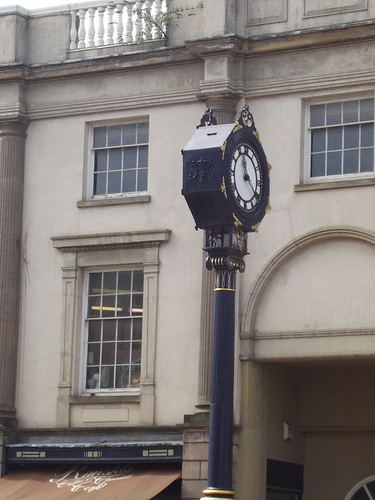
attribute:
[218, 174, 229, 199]
details — gold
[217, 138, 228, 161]
details — gold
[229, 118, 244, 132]
details — gold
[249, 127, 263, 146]
details — gold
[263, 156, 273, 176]
details — gold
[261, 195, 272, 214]
details — gold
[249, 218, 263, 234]
details — gold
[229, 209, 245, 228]
details — gold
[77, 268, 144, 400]
window — white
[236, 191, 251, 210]
numerals — roman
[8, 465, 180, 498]
awning — brown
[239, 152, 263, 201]
hands — black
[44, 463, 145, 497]
writing — white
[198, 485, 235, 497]
stripes — gold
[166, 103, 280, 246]
clock — black, white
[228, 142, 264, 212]
clock face — white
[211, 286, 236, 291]
stripe — gold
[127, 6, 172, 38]
tree — green  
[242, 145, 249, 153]
roman numeral — black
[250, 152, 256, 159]
roman numeral — black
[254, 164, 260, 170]
roman numeral — black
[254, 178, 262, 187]
roman numeral — black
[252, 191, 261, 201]
roman numeral — black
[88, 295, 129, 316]
light — hanging  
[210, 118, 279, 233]
clock — big  , blue  , white  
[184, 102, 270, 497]
clock — tall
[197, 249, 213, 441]
column — stone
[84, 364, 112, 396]
fan — small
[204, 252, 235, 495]
pole — gold, black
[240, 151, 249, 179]
hand — black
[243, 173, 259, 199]
hand — black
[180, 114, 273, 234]
clock — gold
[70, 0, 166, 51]
decorative railing — white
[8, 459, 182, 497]
awning — faded, brown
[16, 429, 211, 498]
awning — cursive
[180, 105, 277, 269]
clock — embellished, decorated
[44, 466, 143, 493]
text — white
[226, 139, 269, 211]
face — white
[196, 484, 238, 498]
trimming — gold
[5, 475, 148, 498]
fabric — brown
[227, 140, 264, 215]
clock — black